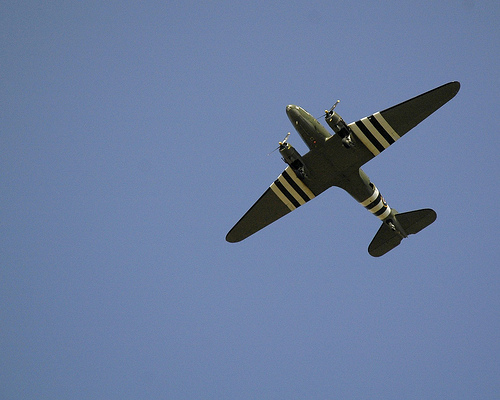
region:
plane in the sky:
[182, 58, 478, 291]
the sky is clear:
[225, 319, 352, 365]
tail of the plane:
[360, 200, 438, 258]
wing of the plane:
[206, 158, 306, 243]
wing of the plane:
[353, 86, 438, 155]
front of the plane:
[272, 93, 332, 149]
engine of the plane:
[261, 131, 300, 166]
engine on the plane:
[324, 99, 348, 133]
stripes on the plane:
[267, 167, 315, 221]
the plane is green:
[325, 160, 348, 174]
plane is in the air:
[207, 80, 457, 255]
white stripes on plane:
[205, 75, 465, 255]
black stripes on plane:
[190, 75, 460, 255]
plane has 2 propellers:
[260, 90, 355, 155]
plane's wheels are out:
[290, 130, 395, 230]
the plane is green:
[210, 71, 461, 256]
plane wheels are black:
[288, 133, 370, 188]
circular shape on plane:
[375, 191, 389, 209]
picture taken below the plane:
[204, 77, 467, 259]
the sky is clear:
[1, 3, 498, 393]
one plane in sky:
[219, 70, 469, 269]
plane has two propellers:
[259, 101, 344, 165]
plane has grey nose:
[263, 104, 300, 122]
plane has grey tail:
[375, 212, 434, 257]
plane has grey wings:
[213, 46, 451, 260]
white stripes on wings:
[252, 113, 383, 210]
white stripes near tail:
[360, 180, 395, 222]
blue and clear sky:
[34, 19, 154, 159]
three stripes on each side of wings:
[268, 109, 390, 217]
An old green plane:
[186, 72, 466, 282]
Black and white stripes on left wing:
[265, 165, 310, 205]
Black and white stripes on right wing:
[345, 110, 397, 150]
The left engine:
[310, 95, 345, 121]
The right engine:
[257, 125, 299, 170]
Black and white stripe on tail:
[359, 184, 399, 223]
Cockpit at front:
[284, 92, 326, 138]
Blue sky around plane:
[61, 28, 203, 123]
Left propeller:
[263, 122, 294, 152]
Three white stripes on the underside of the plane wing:
[345, 110, 406, 162]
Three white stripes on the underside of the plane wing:
[265, 163, 320, 212]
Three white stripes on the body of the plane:
[351, 183, 396, 230]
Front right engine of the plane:
[312, 100, 352, 137]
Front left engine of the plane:
[267, 132, 304, 169]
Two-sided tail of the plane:
[353, 205, 445, 270]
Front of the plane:
[277, 95, 330, 150]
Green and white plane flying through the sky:
[220, 73, 474, 271]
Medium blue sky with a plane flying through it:
[0, 0, 499, 399]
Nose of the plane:
[278, 102, 300, 115]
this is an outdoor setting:
[22, 20, 464, 320]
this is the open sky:
[42, 52, 259, 368]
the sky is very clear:
[6, 48, 181, 241]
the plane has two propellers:
[269, 92, 376, 164]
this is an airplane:
[61, 38, 451, 374]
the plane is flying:
[230, 77, 442, 308]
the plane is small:
[216, 55, 496, 276]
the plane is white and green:
[245, 50, 461, 275]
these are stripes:
[241, 155, 318, 220]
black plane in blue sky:
[199, 53, 469, 281]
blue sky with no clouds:
[40, 107, 84, 152]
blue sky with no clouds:
[233, 304, 268, 339]